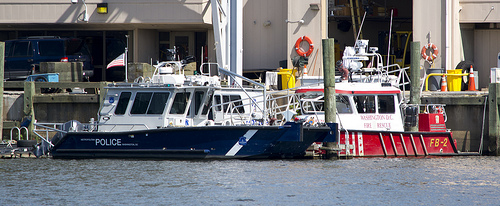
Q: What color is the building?
A: Tan.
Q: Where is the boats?
A: In the water.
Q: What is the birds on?
A: No birds seen.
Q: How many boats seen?
A: Two.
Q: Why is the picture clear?
A: Good camera.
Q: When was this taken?
A: Day time.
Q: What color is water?
A: Green.